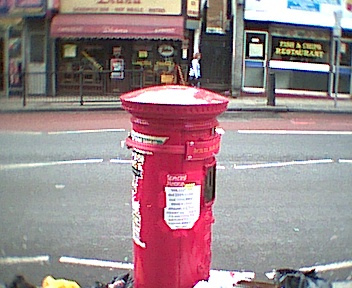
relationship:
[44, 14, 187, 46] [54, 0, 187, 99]
awning on front of building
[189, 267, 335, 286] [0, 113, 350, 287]
garbage laying on street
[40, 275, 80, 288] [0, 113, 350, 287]
garbage laying on street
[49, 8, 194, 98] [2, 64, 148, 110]
storefront behind fence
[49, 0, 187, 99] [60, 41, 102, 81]
building has window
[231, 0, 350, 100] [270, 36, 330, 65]
building has window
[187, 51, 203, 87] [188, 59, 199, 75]
woman wearing jacket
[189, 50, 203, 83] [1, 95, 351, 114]
woman standing on sidewalk